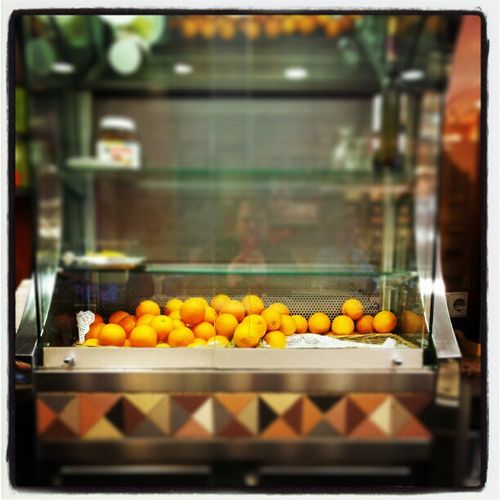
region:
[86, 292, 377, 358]
Oranges are in rack.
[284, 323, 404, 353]
Paper is under the orange.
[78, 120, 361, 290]
Reflection is seen in glass.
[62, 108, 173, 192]
Bottle has white lable.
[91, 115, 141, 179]
Sauce is brown color.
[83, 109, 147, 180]
Jam bottle is top shelf.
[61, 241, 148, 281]
Tray is white color.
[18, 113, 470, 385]
Rack is made of metal and glass.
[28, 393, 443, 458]
Design in bottom of rack.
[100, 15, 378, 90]
Reflection is seen in top glass.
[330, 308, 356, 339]
This is a orange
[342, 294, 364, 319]
This is a orange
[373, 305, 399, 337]
This is a orange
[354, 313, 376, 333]
This is a orange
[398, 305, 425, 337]
This is a orange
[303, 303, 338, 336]
This is a orange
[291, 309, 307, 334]
This is a orange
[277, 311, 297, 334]
This is a orange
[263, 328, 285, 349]
This is a orange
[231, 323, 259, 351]
This is a orange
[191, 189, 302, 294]
photographer reflected in glass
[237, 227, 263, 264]
photographer has red mobile phone [or cellphone in red case]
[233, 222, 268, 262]
photographer uses cellphone to capture vertical picture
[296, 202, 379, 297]
another person captured in reflection, looking away from photo+photographer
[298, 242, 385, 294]
other reflected individual wears button down shirt in blues+whites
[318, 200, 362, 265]
individual reflected is woman w/ curly blonde hair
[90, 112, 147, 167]
very blurry jar of nutella on shelf stands alone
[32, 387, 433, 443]
front of shelf has mosaic tile strip of triangles in warm colours+black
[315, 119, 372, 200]
two bottles blurrily reflected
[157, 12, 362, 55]
a reflection of the oranges @ bottom in window or mirror @ top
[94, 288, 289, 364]
oranges stacked in bin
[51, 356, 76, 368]
metal piece on bin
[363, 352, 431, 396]
silver item on bin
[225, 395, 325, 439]
bin has design on front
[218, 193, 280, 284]
reflection of guy in glass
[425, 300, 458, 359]
metal enclosure of bin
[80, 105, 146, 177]
jar of nutella on shelf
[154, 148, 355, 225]
shelf is of glass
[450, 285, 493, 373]
white knob on wall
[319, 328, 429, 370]
basket in bin with oranges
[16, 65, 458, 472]
A display cabinet filled with oranges.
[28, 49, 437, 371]
A glass door on the front of the case.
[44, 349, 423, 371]
Two knobs on the lower front of the glass door.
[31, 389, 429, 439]
Triangular shapes on the lower front of the display case.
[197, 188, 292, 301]
A reflection of a man holding a red cup.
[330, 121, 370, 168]
The reflection of a man wearing white clothing.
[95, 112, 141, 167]
A container with a white lid.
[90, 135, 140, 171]
A label with red lettering on a brown container.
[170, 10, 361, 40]
Oranges reflecting onto the upper part of the glass.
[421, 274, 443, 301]
light reflecting off of metal on the display case.